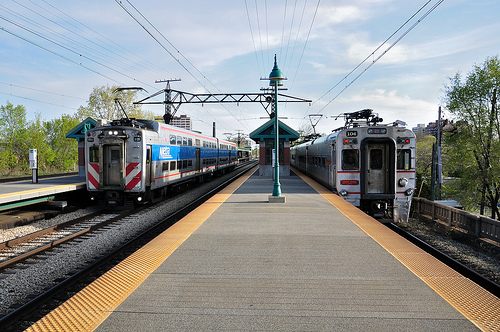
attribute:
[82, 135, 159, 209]
train — striped, back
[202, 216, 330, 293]
platform — wooden, between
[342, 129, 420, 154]
lights — red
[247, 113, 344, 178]
hut — small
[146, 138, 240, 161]
stripes — blue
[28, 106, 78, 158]
leaves — green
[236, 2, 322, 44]
lines — power, bunched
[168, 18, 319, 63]
clouds — wispy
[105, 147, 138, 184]
door — back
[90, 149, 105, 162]
window — glass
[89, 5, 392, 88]
sky — full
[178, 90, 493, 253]
station — here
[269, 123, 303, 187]
post — green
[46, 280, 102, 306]
rail — black